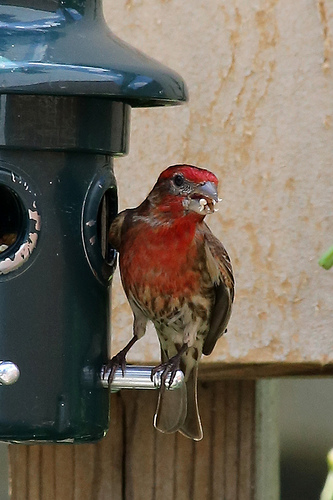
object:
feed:
[199, 193, 223, 211]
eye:
[172, 174, 183, 188]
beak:
[189, 180, 219, 216]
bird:
[102, 164, 235, 441]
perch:
[101, 363, 185, 391]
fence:
[9, 375, 255, 498]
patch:
[121, 216, 197, 303]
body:
[117, 212, 212, 347]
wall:
[103, 1, 333, 366]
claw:
[150, 354, 186, 390]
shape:
[0, 162, 41, 274]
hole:
[96, 187, 118, 264]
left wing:
[201, 230, 235, 355]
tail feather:
[150, 345, 188, 434]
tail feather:
[177, 359, 204, 441]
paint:
[0, 167, 42, 284]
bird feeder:
[0, 0, 189, 445]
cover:
[0, 0, 190, 109]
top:
[157, 162, 219, 186]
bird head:
[157, 163, 219, 217]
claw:
[102, 349, 128, 385]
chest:
[124, 214, 203, 284]